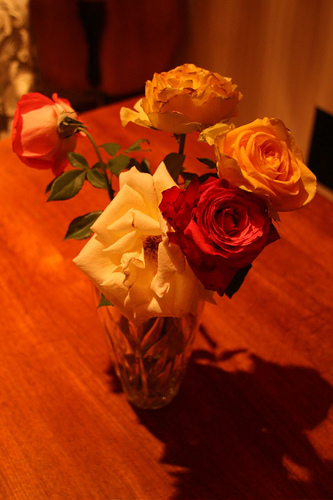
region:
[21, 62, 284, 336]
flowers in a vase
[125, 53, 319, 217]
two yellow roses in a vase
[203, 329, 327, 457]
the shadow from the roses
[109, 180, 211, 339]
a white wilted rose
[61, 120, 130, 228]
the stem and leaves of the rose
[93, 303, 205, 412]
a clear crystal vase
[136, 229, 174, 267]
the center of the rose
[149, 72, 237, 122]
the brown wilting of the rose petals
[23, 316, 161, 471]
the brown wood table the vase is sitting on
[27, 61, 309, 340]
a vase with five roses in it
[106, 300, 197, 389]
the vase has water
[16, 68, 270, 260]
different colored flowers on the table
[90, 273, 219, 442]
vase on the table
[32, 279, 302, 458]
the table is brown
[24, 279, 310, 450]
the table is wooden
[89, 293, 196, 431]
the vase is glass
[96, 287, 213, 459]
the vase is clear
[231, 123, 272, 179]
the flower is orange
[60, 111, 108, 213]
the flower stem is green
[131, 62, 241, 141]
a yellow petal on a flower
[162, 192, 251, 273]
the red petal on a flower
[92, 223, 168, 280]
the white petal on a flower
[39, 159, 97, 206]
a bunch of green leaves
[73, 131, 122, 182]
the stem on a flower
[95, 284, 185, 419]
a glass flower vase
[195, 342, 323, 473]
the shadow of a flower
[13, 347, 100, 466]
the wood on a tabletop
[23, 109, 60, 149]
the pink petal of a flower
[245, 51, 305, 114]
the cream color of a wall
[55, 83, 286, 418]
A glass vase with five roses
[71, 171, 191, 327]
A white fully blossomed rose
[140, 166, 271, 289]
A red rose with dark red edges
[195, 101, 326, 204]
A peach rose with browning edges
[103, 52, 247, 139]
A light pink rose with brown edges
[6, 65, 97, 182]
A pink rose seen from behind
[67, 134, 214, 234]
A group of several rose stems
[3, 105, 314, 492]
A wooden dining room table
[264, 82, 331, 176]
A dark colored dining room chair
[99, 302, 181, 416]
A geometric carved glass vase